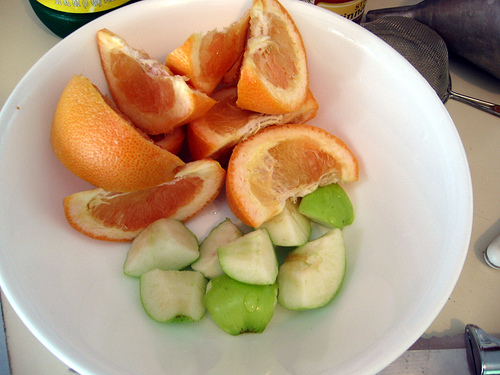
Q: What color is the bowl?
A: White.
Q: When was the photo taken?
A: Daytime.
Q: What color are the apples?
A: Green.